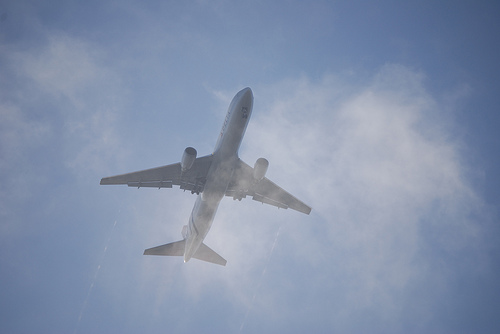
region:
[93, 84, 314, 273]
an airplane in the sky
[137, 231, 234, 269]
the tail of an airplane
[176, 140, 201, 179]
an engine on the plane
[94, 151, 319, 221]
the wings of a plane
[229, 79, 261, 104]
the nose of a plane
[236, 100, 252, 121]
the landing gear of a plane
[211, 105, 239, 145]
writing on the plane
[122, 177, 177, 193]
the flaps of a plane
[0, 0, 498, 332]
a pale blue sky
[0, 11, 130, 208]
cloud in the sky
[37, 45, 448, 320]
a huge plane in the sky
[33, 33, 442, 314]
a large plane in the sky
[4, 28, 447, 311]
a powerful plane in the sky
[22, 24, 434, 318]
a full size plane in the sky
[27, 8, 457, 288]
a huge airplane in the blue sky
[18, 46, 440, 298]
a large airplane in the blue sky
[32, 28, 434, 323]
a powerful airplane in the blue sky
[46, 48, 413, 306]
a full size airplane in the blue sky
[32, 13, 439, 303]
an airplane flying in the blue sky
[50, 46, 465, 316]
huge airplane in the beautiful blue sky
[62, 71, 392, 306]
white airplane in the clouds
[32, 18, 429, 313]
airplane flying in the sky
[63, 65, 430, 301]
white airplane flying in the air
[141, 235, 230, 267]
tail of the airplane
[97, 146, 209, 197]
white right wing on plane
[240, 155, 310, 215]
left wing on airplane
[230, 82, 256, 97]
nose of white airplane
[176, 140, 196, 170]
right engine on the wing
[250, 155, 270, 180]
left engine on wing of airplane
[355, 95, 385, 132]
a cloud in the sky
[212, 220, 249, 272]
a cloud in the sky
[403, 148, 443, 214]
a cloud in the sky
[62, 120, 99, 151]
a cloud in the sky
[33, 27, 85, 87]
a cloud in the sky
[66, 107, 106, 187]
a cloud in the sky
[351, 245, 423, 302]
a cloud in the sky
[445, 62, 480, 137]
a cloud in the sky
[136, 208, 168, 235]
a cloud in the sky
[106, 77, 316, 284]
a plane in the sky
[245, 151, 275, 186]
the engine of a plane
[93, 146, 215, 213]
the wing of a plane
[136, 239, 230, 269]
the tail of a plane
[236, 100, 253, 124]
the front wheel of the plane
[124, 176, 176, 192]
landing flap of the plane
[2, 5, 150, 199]
a white cloud in the sky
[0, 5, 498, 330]
a blue sky